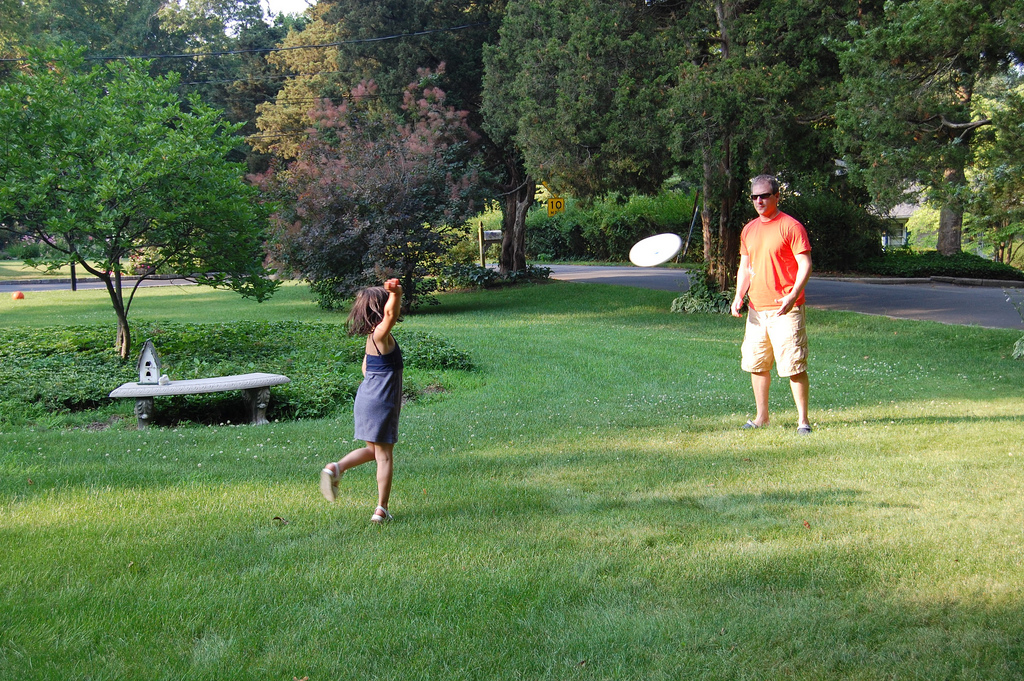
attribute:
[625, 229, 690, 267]
frisbee — white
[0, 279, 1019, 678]
grass — short, green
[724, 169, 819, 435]
man — standing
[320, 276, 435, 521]
kid — little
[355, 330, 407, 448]
dress — blue